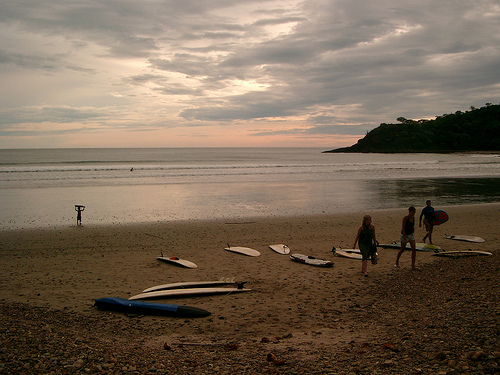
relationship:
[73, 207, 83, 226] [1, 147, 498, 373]
child on beach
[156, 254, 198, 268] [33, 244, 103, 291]
board on beach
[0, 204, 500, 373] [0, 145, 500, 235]
sand on water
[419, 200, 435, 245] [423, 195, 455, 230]
man on surfboard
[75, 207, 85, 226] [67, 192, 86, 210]
child on surf board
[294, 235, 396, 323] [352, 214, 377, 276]
board on man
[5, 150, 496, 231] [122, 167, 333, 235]
water on shore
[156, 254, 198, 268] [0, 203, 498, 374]
board on beach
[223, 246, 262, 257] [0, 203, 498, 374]
board on beach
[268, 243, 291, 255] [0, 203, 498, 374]
board on beach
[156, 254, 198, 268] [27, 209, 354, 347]
board on beach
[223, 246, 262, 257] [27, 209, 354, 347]
board on beach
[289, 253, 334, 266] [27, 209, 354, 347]
board on beach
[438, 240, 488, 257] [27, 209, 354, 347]
surfboard on beach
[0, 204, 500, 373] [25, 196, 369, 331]
sand on beach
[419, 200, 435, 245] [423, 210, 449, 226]
man carrying surfboard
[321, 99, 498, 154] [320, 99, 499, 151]
trees are on hill.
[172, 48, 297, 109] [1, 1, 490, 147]
clouds are in sky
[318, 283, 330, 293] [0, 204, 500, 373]
footstep in sand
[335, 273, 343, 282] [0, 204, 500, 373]
footstep in sand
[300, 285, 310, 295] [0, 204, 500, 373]
footstep in sand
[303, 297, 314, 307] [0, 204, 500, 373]
footstep in sand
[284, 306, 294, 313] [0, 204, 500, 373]
footstep in sand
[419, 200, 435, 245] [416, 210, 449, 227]
man with surfboard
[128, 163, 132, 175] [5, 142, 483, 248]
person in ocean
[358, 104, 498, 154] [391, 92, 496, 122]
elevated area with trees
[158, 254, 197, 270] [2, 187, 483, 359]
board in sand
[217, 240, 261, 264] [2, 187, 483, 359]
board in sand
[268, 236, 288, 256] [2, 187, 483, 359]
board in sand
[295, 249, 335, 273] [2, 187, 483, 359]
board in sand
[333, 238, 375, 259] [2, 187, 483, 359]
board in sand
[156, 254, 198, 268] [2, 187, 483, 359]
board on sand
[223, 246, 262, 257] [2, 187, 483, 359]
board on sand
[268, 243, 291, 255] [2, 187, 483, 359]
board on sand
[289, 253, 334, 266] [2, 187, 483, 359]
board on sand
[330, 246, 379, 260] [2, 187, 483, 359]
board on sand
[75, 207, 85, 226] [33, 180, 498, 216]
child in water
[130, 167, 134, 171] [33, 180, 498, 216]
person in water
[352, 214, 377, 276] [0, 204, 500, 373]
man on sand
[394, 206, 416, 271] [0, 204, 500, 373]
people on sand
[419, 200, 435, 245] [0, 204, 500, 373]
man on sand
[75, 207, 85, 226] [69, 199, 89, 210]
child had board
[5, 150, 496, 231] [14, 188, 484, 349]
water by beach